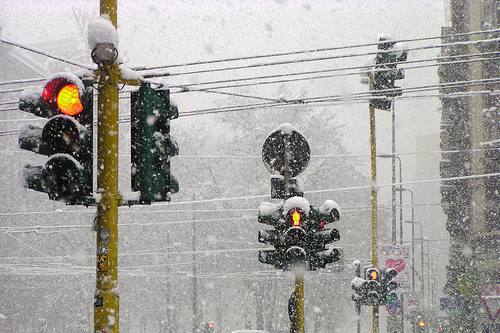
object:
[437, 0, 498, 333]
building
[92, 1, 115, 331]
pole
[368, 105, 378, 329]
pole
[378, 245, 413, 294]
sign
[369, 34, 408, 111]
street light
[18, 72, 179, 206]
traffic light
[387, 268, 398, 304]
traffic light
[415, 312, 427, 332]
traffic light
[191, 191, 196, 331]
wooden pole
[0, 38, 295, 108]
lines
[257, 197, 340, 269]
traffic light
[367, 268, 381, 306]
traffic light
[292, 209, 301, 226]
light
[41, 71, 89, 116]
light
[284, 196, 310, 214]
snow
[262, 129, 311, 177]
sign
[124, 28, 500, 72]
wire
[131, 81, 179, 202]
traffic signal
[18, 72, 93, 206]
traffic signal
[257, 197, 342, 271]
traffic signal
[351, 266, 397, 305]
traffic signal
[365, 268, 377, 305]
traffic signal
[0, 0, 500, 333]
snow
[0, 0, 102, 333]
side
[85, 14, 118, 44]
snow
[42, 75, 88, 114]
signal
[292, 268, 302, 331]
pole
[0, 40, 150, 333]
building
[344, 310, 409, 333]
road